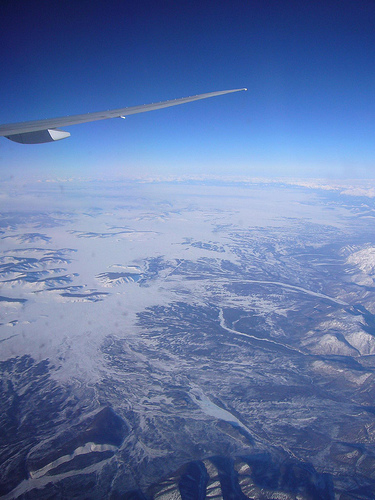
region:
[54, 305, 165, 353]
A rocky water valley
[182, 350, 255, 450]
A rocky water valley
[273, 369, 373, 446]
A rocky water valley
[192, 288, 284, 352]
A rocky water valley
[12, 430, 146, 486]
A rocky water valley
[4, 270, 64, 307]
A rocky water valley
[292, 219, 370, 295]
A rocky water valley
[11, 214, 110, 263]
A rocky water valley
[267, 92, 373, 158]
A blue clear sky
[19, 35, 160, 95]
A blue clear sky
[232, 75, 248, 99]
Silver and black bag in the sky.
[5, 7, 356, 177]
The sky is clear blue.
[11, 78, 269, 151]
The wing to a plane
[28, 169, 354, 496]
The Earth is down below.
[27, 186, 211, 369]
The clouds are white.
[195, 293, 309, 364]
The river is blue.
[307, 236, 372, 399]
the mountains are brown.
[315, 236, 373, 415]
The mountains are high.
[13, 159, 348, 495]
The Earth from up high.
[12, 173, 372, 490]
The terrain is varied.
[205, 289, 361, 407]
The river is running from the mountain.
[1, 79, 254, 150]
the left wing of an airplane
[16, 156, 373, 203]
distant clouds in the sky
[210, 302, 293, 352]
a river on the ground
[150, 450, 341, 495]
sharp rocks on the mountains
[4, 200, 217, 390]
a large patch of snow on the mountains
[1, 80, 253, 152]
the airplane wing is white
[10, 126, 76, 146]
a vent under the airplane wing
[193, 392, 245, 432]
a pile of snow on a mountain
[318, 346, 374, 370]
a deep valley between mountains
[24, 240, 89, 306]
snow covering mountains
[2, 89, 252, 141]
the wing of an airplane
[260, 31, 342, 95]
an area of blue sky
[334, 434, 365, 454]
the shadow on the other side of a mountain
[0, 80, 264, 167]
the right wing of an airplane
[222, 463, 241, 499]
a valley between two mountain ravines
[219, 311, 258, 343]
a frozen river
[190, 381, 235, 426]
a frozen lake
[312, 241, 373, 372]
a mountain range with snow